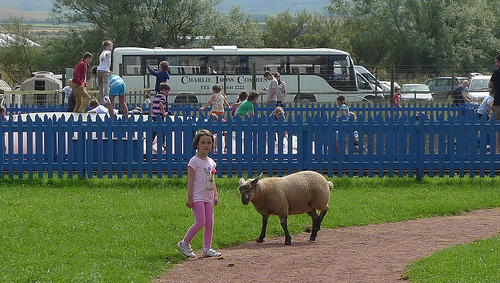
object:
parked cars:
[390, 79, 439, 109]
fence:
[5, 56, 495, 109]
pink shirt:
[177, 151, 229, 210]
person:
[81, 60, 138, 126]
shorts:
[103, 81, 132, 98]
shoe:
[169, 238, 202, 261]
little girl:
[197, 81, 234, 124]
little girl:
[326, 90, 376, 156]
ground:
[344, 227, 375, 239]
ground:
[321, 249, 341, 265]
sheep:
[227, 164, 344, 250]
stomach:
[195, 186, 217, 202]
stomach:
[287, 196, 316, 214]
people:
[41, 40, 373, 161]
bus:
[101, 39, 373, 110]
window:
[321, 53, 354, 84]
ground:
[343, 231, 408, 282]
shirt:
[140, 60, 178, 96]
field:
[7, 0, 480, 47]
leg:
[176, 199, 211, 246]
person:
[64, 45, 99, 119]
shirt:
[65, 57, 92, 89]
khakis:
[67, 79, 94, 115]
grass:
[14, 181, 117, 281]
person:
[228, 88, 266, 135]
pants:
[178, 198, 220, 254]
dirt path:
[144, 203, 499, 282]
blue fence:
[0, 95, 499, 191]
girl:
[157, 124, 242, 264]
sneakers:
[196, 244, 231, 261]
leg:
[198, 199, 221, 254]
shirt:
[230, 98, 259, 121]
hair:
[187, 125, 224, 155]